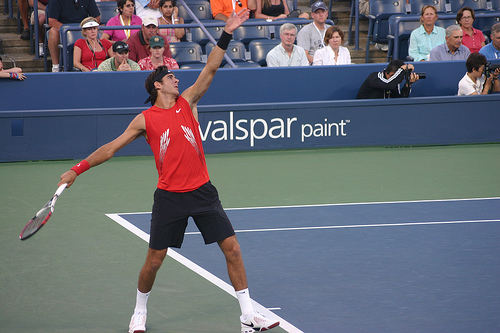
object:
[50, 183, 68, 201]
handle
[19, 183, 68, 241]
racket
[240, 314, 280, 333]
shoe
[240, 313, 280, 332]
man's foot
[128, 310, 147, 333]
man's foot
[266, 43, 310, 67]
shirt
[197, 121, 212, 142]
letter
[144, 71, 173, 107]
head band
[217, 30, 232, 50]
arm band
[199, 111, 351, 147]
advertisement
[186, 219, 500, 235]
line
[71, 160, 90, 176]
armband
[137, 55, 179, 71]
shirt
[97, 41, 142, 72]
man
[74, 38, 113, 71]
shirt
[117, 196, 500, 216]
line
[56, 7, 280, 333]
man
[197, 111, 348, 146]
name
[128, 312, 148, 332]
shoe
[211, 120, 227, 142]
letters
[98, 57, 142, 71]
shirt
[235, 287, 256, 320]
socks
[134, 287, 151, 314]
socks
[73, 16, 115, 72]
woman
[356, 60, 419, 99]
man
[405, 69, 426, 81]
camera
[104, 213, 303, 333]
lines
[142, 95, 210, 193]
tank top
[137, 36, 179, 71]
spectators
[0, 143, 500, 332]
court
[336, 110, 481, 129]
wall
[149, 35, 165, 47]
hat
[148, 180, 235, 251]
shorts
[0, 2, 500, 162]
stands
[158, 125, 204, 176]
design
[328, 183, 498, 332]
ground